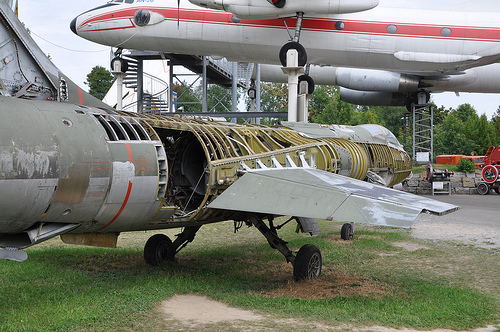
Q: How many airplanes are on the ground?
A: One.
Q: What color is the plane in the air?
A: Red and white.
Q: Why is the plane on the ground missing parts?
A: Because it is damaged.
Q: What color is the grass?
A: Green.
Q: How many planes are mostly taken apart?
A: 1.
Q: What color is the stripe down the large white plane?
A: Red.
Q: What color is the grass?
A: Green.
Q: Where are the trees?
A: In background.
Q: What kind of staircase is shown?
A: Spiral.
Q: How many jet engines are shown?
A: 3.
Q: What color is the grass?
A: Green.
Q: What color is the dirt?
A: Brown.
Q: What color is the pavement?
A: Gray.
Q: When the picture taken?
A: Daytime.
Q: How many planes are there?
A: Two.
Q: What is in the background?
A: Trees.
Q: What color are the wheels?
A: Black.